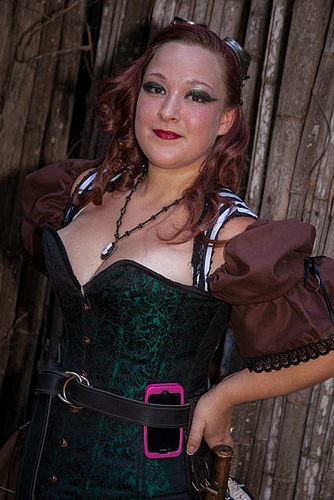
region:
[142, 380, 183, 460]
cell phone has pink cover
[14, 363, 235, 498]
woman is wearing belt with attachments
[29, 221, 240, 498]
woman is wearing corset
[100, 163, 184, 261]
necklace has white figure on it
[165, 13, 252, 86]
woman has goggles on head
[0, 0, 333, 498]
wall is wooden and white wash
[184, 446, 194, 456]
long finger nail on thumb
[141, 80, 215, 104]
woman has green eyes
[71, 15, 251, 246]
woman has red glittery styled hair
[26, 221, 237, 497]
corset is green and black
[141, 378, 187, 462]
A pink smart phone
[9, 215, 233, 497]
A dark green corset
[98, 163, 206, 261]
A cameo necklace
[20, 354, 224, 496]
A thick black belt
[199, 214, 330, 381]
A brown puffy sleeve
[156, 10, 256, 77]
A pair of goggles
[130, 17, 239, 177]
A face of a woman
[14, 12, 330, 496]
A woman in a costume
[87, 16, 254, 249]
Some curly red hair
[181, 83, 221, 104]
Dark green eyshadow makeup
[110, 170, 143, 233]
woman wearing a necklace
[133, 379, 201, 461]
cellphone in her belt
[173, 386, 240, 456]
woman's hand is on her hip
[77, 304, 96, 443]
buttons on the dress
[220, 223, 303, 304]
red puffy sleeves on the dress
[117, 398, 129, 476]
dress is green and black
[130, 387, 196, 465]
phone cover is purple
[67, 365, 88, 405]
two silver rings on her belt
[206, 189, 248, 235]
straps are white and black striped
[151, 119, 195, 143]
woman is wearing red lipstick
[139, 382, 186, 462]
Iphone with pink case.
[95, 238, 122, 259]
Black and white silhouette pendant.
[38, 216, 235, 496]
Green and black corset.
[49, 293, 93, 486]
Clasp on front of corset.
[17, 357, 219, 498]
Black leather belt with metal clips.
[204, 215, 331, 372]
Brown and black lace sleeve.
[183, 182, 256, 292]
Black and white striped straps.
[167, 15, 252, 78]
Goggles on top of woman's head.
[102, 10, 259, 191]
Woman with red hair.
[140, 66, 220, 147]
Woman with red lipstick and green eye shadow.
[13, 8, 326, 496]
a girl pirate with a cellphone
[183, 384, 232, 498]
a sword is hanging on the belt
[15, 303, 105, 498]
the sword is on a black belt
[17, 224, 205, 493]
a green and black bustier is on the girl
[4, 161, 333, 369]
the costume has puffy sleeves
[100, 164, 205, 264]
the pirate is wearing a black necklace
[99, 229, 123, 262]
the necklace has a cameo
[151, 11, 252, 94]
goggles are on the girl's head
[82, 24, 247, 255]
the woman's hair is brown and curly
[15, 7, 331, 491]
a worn wooden fence is behind the girl